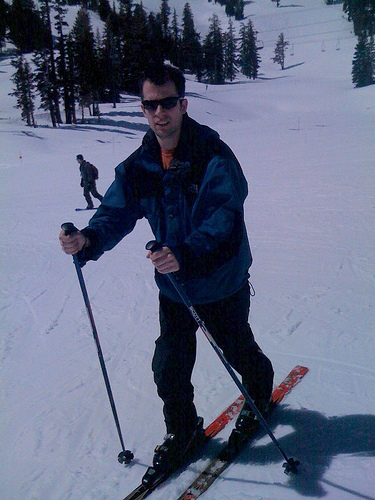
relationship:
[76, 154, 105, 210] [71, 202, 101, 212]
man on snowboard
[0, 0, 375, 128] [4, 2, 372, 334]
evergreen trees in snow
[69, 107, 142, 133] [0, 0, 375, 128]
shadow of evergreen trees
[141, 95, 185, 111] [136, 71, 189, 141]
eyeglass on face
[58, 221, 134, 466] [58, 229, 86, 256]
pole in hand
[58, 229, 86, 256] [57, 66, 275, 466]
hand of man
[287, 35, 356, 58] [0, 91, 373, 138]
lift chairs travelling through air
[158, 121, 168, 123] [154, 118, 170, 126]
teeth in mouth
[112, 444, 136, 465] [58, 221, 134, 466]
disk grip on pole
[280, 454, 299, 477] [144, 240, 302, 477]
grip on poles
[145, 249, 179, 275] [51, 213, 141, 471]
hand grasping ski pole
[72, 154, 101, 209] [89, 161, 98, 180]
man carrying backpack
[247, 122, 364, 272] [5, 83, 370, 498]
snow on ground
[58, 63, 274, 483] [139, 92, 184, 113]
he wearing goggles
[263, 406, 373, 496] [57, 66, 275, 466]
shadow of man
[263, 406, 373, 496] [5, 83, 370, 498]
shadow on ground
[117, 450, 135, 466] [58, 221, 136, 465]
end of pole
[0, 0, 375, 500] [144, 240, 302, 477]
snow on poles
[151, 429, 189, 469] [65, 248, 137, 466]
shoe on pole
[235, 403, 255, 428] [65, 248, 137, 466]
shoe on pole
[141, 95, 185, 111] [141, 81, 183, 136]
eyeglass on face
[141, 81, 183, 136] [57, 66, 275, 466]
face of man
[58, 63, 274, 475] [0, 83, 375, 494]
he walking on snow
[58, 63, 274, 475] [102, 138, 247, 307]
he wearing jacket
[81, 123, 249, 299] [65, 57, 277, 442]
jacket worn by man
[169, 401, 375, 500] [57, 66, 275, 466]
shadow from man